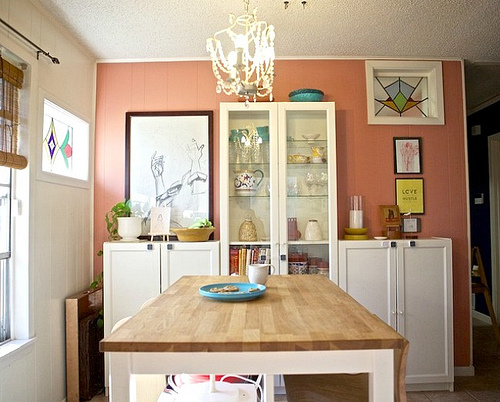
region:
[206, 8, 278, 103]
a chandelier hanging from the ceiling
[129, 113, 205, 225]
a picture hanging on the wall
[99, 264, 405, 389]
a table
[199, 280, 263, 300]
a blue plate on the table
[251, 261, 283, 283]
a white mug on the table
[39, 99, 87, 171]
a window on the wall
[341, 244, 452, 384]
a white cabinet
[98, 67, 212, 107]
a pink wall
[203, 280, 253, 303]
a plate of cookies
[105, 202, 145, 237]
a plant in a white vase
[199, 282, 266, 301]
a round blue plate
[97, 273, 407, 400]
a butcher block kitchen table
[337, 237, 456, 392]
a short white cabinet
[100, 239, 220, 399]
a short white cabinet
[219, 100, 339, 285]
a glass curio cabinet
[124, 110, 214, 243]
a framed drawing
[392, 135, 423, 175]
a small framed print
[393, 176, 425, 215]
a small framed print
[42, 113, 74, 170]
an inset stained glass window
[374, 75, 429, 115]
an inset stained glass window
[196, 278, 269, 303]
blue plate on the table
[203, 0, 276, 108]
white chandelier hanging from the ceiling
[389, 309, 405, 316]
white knobs on the cabinet doors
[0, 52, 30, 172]
bamboo blinds on the window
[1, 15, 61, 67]
black curtain rod above the window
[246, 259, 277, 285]
white cup on the table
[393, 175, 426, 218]
yellow picture on the wall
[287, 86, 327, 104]
blue bowl on top of the cabinet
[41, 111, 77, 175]
stained glass window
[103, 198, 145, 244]
green plant in a white pot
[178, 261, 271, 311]
this is a blue plate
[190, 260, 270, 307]
the plate is round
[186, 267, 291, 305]
the plate is blue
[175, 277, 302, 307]
a round blue plate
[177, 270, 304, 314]
a round and blue plate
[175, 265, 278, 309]
there are cookies on the plate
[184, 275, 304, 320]
cookies on a blue plate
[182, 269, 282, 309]
cookies on a round blue plate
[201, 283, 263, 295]
these are cookies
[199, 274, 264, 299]
baked cookies on a blue plate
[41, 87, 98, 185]
A beautiful stained glass window is in the wall.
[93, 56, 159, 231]
The wall is painted a pretty shade of peach.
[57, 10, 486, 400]
One accent wall of the room was painted peach.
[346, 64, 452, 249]
Lots of colorful artwork hangs on the wall.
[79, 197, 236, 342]
The cabinets in the room are all painted white.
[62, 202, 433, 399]
A nice sized butcher block dining table in the center of the room.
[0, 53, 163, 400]
Lots of natural light in this dining room area.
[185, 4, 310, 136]
A simple chandelier hangs from the ceiling..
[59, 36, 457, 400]
The room is decorated in peach and white with pops of turquoise.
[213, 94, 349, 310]
The cabinet with glass windows displays collectible items.